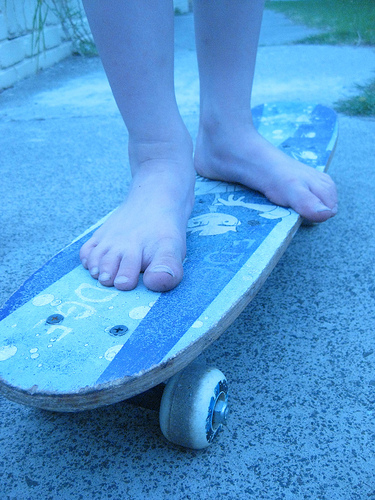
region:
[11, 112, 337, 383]
A blue skateboard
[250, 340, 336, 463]
Cement beneath the skateboard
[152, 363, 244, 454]
Wheels on the skateboard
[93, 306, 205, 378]
Blue stripe on the skateboard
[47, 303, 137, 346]
Two screws in the board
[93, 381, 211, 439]
Axle of the skateboard's wheels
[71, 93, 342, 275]
The person is barefoot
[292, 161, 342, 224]
Toes hanging close to the ground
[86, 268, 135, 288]
Well trimmed toenails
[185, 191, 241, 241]
Logo on the skateboard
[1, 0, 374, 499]
why is this picture blue? but it is.....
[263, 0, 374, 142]
lawn, lots of it, in the middle distance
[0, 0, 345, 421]
two bare feet on one beginning to be beat down board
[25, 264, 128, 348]
'dge'; above it 'edg'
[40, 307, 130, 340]
two phillips head screws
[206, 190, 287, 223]
one 4 fingered cartoon hand @ the end of a cartoon arm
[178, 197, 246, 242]
a large eyed anime face in the middle of the skateboard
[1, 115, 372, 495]
somebody's backyard has a speckled ground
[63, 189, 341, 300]
no toenail polish on reasonably clean toes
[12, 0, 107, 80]
a weed grown from where the ground hits the wall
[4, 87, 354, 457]
person on skateboard on ground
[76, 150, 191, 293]
foot of person on skateboard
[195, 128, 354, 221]
foot of person on skateboard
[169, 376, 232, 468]
wheel with bolt on skateboard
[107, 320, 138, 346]
screw on top of board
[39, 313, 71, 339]
screw on top of board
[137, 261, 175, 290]
toe on right foot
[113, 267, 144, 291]
toe on right foot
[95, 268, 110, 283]
toe on right foot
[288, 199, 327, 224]
toe on left foot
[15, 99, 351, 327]
Feet on a skateboard.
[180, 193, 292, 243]
Person on a skateboard.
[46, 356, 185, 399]
The paint is coming off.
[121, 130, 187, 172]
Lines on the leg.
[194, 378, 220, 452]
White on the wheel.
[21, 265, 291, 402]
The skateboard is wooden.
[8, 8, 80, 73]
The wall is brick.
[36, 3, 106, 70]
Weeds by the wall.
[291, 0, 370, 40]
The grass is green.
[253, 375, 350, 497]
The road is paved.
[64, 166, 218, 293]
leg of the person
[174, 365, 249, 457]
a small wheel of the machine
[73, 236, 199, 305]
fingers of the man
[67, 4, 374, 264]
a part of the leg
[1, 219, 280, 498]
a nice skating machine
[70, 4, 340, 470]
a person standing on machine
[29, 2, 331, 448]
skating machine in which a person is standing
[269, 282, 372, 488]
beautiful view of floor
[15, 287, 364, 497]
a very clean floor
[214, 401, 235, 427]
nut of the wheel